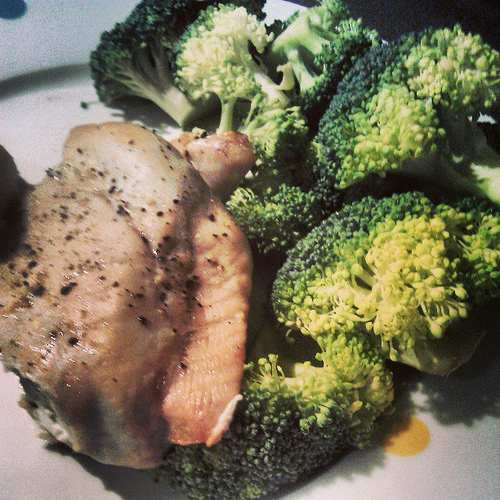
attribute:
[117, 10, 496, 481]
broccoli — bunch, green, raw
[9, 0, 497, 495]
plate — white, circular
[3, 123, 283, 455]
meat — light brown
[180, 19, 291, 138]
part — white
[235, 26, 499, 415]
part — dark green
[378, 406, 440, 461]
dot — orange, circular, yellow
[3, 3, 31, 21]
dot — blue, small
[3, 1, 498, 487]
meal — healthy, broccoli, meat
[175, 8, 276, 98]
piece — white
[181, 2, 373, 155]
florets — white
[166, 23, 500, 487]
florets — dark green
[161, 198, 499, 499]
florets — light green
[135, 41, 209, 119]
stem — green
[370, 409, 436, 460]
spot — yellow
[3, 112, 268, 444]
beef — cooked, seasoned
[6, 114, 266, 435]
pork — cut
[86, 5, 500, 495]
colors — dark green, light green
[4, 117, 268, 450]
chicken — seasoned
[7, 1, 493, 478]
food — ready